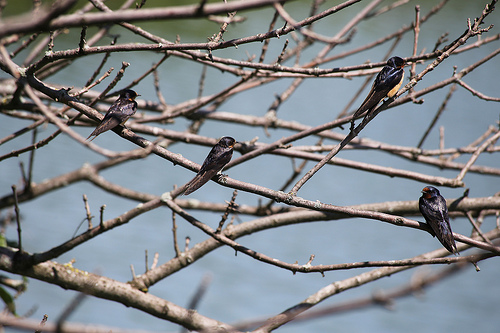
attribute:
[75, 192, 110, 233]
twigs — smaller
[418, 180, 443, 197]
bird head — dark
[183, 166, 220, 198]
bird tail — brownish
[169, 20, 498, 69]
branches — thin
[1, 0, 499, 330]
tree branches — brown, bare, wooden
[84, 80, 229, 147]
bird — black 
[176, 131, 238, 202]
bird — black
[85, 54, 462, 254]
four birds — black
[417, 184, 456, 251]
bird — small, dark, black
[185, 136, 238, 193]
bird — small, black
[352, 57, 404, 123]
bird — small, dark, black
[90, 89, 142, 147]
bird — small, dark, black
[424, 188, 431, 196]
face — red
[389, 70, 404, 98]
underbelly — tan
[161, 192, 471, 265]
branch — small, thin, long, leafless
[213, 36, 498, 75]
branch — small, thin, long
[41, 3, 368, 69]
branch — small, thin, long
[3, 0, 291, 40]
branch — long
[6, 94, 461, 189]
branch — long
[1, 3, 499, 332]
sky — blue, clear blue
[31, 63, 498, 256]
branch — long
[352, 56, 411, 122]
bird — black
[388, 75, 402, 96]
breast — yellow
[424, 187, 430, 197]
beaks — orange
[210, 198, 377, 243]
branches — bare brown 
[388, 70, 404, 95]
chest — yellow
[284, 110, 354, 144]
branch — brown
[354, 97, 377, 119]
tail — long